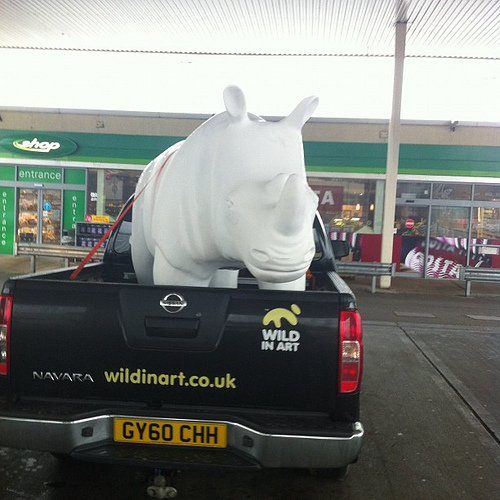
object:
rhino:
[126, 84, 321, 289]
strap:
[68, 155, 175, 282]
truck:
[0, 187, 363, 495]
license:
[113, 417, 229, 450]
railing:
[11, 239, 106, 279]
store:
[3, 102, 500, 288]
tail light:
[340, 336, 361, 364]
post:
[373, 21, 404, 289]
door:
[12, 181, 60, 254]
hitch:
[145, 471, 179, 499]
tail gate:
[6, 276, 337, 422]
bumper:
[0, 402, 362, 479]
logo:
[258, 300, 303, 353]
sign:
[0, 131, 82, 160]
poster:
[314, 185, 344, 211]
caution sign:
[403, 217, 416, 231]